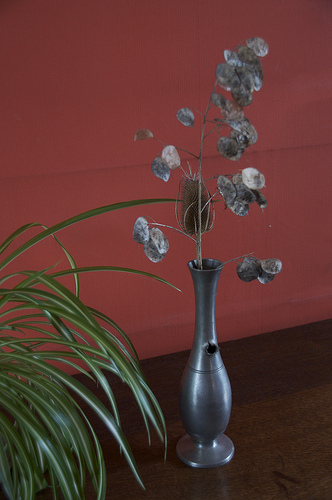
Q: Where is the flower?
A: Left side of the image.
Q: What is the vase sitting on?
A: Table.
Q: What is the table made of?
A: Wood.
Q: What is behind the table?
A: Wall.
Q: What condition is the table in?
A: Dusty.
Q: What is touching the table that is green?
A: The plant on the left.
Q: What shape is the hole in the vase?
A: Round.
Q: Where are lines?
A: On the wall.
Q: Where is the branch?
A: In the vase.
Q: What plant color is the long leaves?
A: Green.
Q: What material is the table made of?
A: Wood.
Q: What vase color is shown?
A: Silver.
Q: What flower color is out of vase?
A: Silver.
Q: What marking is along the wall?
A: Line.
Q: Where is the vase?
A: On a wooden surface.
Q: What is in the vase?
A: Dry plants.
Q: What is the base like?
A: Long and narrow.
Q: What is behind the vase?
A: Red wall.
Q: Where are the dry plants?
A: In the vase.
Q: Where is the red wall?
A: Behind the vase.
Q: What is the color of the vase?
A: Silver.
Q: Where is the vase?
A: On the table.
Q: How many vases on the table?
A: One.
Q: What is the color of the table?
A: Brown.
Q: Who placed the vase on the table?
A: A person.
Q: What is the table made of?
A: Wood.